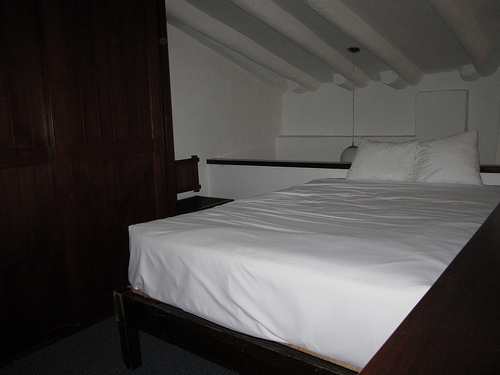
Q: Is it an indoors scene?
A: Yes, it is indoors.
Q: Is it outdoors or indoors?
A: It is indoors.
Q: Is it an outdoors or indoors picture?
A: It is indoors.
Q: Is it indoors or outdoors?
A: It is indoors.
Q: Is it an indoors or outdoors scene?
A: It is indoors.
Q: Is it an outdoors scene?
A: No, it is indoors.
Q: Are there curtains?
A: No, there are no curtains.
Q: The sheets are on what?
A: The sheets are on the bed.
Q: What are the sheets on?
A: The sheets are on the bed.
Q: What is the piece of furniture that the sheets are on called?
A: The piece of furniture is a bed.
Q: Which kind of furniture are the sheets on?
A: The sheets are on the bed.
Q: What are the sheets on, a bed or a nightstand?
A: The sheets are on a bed.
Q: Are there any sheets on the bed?
A: Yes, there are sheets on the bed.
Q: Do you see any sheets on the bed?
A: Yes, there are sheets on the bed.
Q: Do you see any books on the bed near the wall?
A: No, there are sheets on the bed.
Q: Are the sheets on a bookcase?
A: No, the sheets are on the bed.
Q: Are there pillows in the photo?
A: Yes, there is a pillow.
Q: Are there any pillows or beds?
A: Yes, there is a pillow.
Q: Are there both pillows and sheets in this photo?
A: Yes, there are both a pillow and a sheet.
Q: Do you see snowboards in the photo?
A: No, there are no snowboards.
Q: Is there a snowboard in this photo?
A: No, there are no snowboards.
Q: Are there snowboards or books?
A: No, there are no snowboards or books.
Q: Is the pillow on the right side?
A: Yes, the pillow is on the right of the image.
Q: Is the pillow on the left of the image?
A: No, the pillow is on the right of the image.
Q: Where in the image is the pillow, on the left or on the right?
A: The pillow is on the right of the image.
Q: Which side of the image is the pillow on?
A: The pillow is on the right of the image.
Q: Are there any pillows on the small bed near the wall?
A: Yes, there is a pillow on the bed.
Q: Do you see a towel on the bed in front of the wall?
A: No, there is a pillow on the bed.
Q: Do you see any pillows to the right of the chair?
A: Yes, there is a pillow to the right of the chair.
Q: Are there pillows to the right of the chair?
A: Yes, there is a pillow to the right of the chair.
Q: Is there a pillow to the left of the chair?
A: No, the pillow is to the right of the chair.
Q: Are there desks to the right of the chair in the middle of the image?
A: No, there is a pillow to the right of the chair.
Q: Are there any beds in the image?
A: Yes, there is a bed.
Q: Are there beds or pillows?
A: Yes, there is a bed.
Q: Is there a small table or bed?
A: Yes, there is a small bed.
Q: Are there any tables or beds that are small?
A: Yes, the bed is small.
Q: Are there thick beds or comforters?
A: Yes, there is a thick bed.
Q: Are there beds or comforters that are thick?
A: Yes, the bed is thick.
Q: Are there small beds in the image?
A: Yes, there is a small bed.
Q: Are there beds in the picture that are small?
A: Yes, there is a bed that is small.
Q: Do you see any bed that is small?
A: Yes, there is a bed that is small.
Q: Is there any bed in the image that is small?
A: Yes, there is a bed that is small.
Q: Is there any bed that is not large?
A: Yes, there is a small bed.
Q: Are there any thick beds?
A: Yes, there is a thick bed.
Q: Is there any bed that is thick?
A: Yes, there is a bed that is thick.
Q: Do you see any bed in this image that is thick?
A: Yes, there is a bed that is thick.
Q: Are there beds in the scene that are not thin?
A: Yes, there is a thick bed.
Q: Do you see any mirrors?
A: No, there are no mirrors.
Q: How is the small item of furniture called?
A: The piece of furniture is a bed.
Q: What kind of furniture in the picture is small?
A: The furniture is a bed.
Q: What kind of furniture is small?
A: The furniture is a bed.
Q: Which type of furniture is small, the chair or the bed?
A: The bed is small.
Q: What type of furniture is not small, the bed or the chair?
A: The chair is not small.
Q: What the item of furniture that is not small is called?
A: The piece of furniture is a chair.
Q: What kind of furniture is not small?
A: The furniture is a chair.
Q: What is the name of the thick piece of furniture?
A: The piece of furniture is a bed.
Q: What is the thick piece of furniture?
A: The piece of furniture is a bed.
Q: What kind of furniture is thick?
A: The furniture is a bed.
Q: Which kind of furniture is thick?
A: The furniture is a bed.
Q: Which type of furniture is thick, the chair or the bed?
A: The bed is thick.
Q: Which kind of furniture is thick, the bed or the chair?
A: The bed is thick.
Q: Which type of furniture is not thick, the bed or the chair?
A: The chair is not thick.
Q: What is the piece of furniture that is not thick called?
A: The piece of furniture is a chair.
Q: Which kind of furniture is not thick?
A: The furniture is a chair.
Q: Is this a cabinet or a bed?
A: This is a bed.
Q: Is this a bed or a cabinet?
A: This is a bed.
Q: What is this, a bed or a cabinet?
A: This is a bed.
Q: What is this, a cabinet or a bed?
A: This is a bed.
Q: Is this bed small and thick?
A: Yes, the bed is small and thick.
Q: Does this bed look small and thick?
A: Yes, the bed is small and thick.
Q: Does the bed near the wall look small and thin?
A: No, the bed is small but thick.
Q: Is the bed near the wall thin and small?
A: No, the bed is small but thick.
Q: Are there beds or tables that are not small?
A: No, there is a bed but it is small.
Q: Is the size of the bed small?
A: Yes, the bed is small.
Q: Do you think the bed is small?
A: Yes, the bed is small.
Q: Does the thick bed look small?
A: Yes, the bed is small.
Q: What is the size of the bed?
A: The bed is small.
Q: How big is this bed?
A: The bed is small.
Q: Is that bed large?
A: No, the bed is small.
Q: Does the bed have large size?
A: No, the bed is small.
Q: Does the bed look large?
A: No, the bed is small.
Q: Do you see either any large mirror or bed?
A: No, there is a bed but it is small.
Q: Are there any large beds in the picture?
A: No, there is a bed but it is small.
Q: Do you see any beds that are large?
A: No, there is a bed but it is small.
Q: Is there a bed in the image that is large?
A: No, there is a bed but it is small.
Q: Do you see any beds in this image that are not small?
A: No, there is a bed but it is small.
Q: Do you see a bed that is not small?
A: No, there is a bed but it is small.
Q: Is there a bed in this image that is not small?
A: No, there is a bed but it is small.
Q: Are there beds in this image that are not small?
A: No, there is a bed but it is small.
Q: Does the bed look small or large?
A: The bed is small.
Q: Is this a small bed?
A: Yes, this is a small bed.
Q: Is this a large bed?
A: No, this is a small bed.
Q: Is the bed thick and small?
A: Yes, the bed is thick and small.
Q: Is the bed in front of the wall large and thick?
A: No, the bed is thick but small.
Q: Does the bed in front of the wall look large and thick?
A: No, the bed is thick but small.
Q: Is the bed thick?
A: Yes, the bed is thick.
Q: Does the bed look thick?
A: Yes, the bed is thick.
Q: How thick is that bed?
A: The bed is thick.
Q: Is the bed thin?
A: No, the bed is thick.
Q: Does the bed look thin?
A: No, the bed is thick.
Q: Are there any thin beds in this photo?
A: No, there is a bed but it is thick.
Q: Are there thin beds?
A: No, there is a bed but it is thick.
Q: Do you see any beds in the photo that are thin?
A: No, there is a bed but it is thick.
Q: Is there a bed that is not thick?
A: No, there is a bed but it is thick.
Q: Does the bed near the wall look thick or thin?
A: The bed is thick.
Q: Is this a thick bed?
A: Yes, this is a thick bed.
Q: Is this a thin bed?
A: No, this is a thick bed.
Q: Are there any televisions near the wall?
A: No, there is a bed near the wall.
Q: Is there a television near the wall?
A: No, there is a bed near the wall.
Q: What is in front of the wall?
A: The bed is in front of the wall.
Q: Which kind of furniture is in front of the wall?
A: The piece of furniture is a bed.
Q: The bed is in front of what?
A: The bed is in front of the wall.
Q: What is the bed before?
A: The bed is in front of the wall.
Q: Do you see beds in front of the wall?
A: Yes, there is a bed in front of the wall.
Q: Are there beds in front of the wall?
A: Yes, there is a bed in front of the wall.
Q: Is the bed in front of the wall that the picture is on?
A: Yes, the bed is in front of the wall.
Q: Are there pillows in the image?
A: Yes, there is a pillow.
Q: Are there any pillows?
A: Yes, there is a pillow.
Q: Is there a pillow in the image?
A: Yes, there is a pillow.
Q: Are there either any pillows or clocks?
A: Yes, there is a pillow.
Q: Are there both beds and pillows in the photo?
A: Yes, there are both a pillow and a bed.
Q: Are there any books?
A: No, there are no books.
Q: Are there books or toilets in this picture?
A: No, there are no books or toilets.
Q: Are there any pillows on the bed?
A: Yes, there is a pillow on the bed.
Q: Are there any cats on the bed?
A: No, there is a pillow on the bed.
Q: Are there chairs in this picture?
A: Yes, there is a chair.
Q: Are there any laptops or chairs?
A: Yes, there is a chair.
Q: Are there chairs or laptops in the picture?
A: Yes, there is a chair.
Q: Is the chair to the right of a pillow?
A: No, the chair is to the left of a pillow.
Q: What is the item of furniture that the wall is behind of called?
A: The piece of furniture is a bed.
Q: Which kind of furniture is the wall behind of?
A: The wall is behind the bed.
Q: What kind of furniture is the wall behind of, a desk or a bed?
A: The wall is behind a bed.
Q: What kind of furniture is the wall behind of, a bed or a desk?
A: The wall is behind a bed.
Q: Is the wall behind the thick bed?
A: Yes, the wall is behind the bed.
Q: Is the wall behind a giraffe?
A: No, the wall is behind the bed.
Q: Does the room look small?
A: Yes, the room is small.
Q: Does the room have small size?
A: Yes, the room is small.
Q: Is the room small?
A: Yes, the room is small.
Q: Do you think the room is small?
A: Yes, the room is small.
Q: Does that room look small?
A: Yes, the room is small.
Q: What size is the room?
A: The room is small.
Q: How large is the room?
A: The room is small.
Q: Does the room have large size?
A: No, the room is small.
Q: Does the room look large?
A: No, the room is small.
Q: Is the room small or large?
A: The room is small.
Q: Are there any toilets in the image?
A: No, there are no toilets.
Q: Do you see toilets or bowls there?
A: No, there are no toilets or bowls.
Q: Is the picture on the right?
A: Yes, the picture is on the right of the image.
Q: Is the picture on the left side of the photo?
A: No, the picture is on the right of the image.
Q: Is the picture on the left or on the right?
A: The picture is on the right of the image.